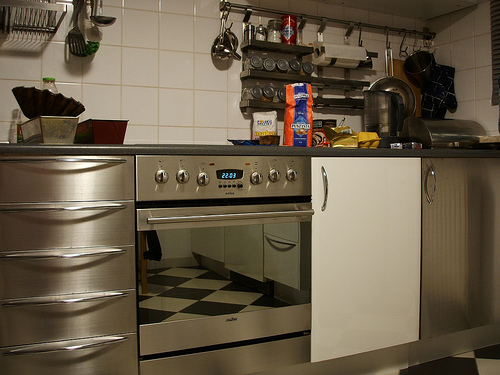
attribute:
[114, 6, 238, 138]
wall — tiled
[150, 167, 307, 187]
oven knobs — metal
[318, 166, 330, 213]
handle — stainless steel, shiny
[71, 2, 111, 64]
utensils — kitchen, hanging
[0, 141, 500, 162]
counter — kitchen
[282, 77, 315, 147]
product — several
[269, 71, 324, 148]
bag — blue, food, red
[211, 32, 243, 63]
silver funnel — hanging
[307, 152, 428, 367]
elephant — silver, white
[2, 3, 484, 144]
tiles — white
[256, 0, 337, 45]
canister — red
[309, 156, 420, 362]
cabinet — kitchen cabinet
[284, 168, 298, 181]
oven knob — metal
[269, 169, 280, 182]
oven knob — metal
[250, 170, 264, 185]
oven knob — metal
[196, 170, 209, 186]
oven knob — metal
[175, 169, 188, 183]
oven knob — metal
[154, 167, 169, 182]
oven knob — metal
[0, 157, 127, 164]
handle — cabinet handle, stainless steel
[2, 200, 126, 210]
handle — cabinet handle, stainless steel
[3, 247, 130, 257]
handle — cabinet handle, stainless steel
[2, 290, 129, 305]
handle — cabinet handle, stainless steel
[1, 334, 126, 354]
handle — cabinet handle, stainless steel